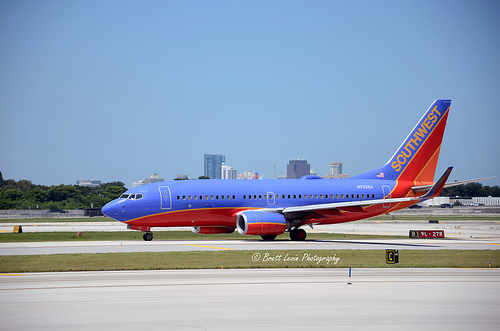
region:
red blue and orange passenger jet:
[79, 90, 449, 249]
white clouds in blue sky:
[16, 20, 76, 60]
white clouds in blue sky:
[6, 62, 101, 131]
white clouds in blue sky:
[25, 105, 99, 165]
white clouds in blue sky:
[101, 130, 183, 182]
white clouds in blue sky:
[76, 6, 167, 64]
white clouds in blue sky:
[204, 19, 295, 56]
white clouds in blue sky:
[194, 83, 283, 122]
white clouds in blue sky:
[318, 18, 438, 84]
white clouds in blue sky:
[287, 84, 380, 136]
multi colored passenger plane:
[100, 83, 441, 242]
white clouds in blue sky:
[11, 15, 114, 90]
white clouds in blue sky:
[119, 16, 216, 65]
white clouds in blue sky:
[116, 63, 219, 109]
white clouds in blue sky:
[224, 6, 303, 44]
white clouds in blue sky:
[237, 54, 327, 112]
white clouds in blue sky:
[329, 6, 458, 55]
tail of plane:
[369, 96, 448, 210]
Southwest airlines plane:
[90, 144, 441, 230]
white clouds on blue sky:
[1, 10, 98, 77]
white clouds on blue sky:
[27, 88, 98, 136]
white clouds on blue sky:
[23, 120, 95, 164]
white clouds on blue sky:
[95, 21, 209, 96]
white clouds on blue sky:
[108, 84, 216, 132]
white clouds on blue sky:
[207, 14, 326, 103]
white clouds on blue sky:
[235, 100, 293, 141]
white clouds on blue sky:
[324, 26, 388, 76]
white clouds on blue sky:
[307, 91, 389, 153]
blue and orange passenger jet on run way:
[70, 89, 459, 234]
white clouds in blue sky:
[12, 9, 74, 46]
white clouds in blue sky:
[7, 70, 73, 108]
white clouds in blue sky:
[98, 95, 171, 159]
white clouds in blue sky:
[88, 35, 150, 93]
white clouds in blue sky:
[178, 14, 280, 75]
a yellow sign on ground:
[9, 225, 25, 237]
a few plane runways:
[20, 185, 415, 315]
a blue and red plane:
[101, 96, 454, 237]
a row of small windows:
[178, 188, 266, 203]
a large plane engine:
[234, 205, 290, 238]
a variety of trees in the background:
[8, 174, 116, 217]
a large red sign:
[405, 228, 450, 240]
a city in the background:
[151, 148, 363, 184]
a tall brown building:
[282, 153, 313, 179]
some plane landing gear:
[286, 224, 311, 246]